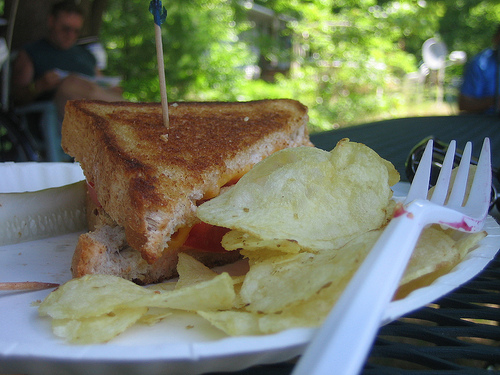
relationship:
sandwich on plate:
[46, 77, 313, 289] [2, 192, 498, 369]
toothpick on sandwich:
[122, 4, 194, 133] [46, 77, 313, 289]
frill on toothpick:
[142, 0, 174, 27] [122, 4, 194, 133]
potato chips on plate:
[30, 153, 464, 324] [2, 192, 498, 369]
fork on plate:
[303, 93, 489, 375] [2, 192, 498, 369]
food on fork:
[381, 187, 478, 240] [303, 93, 489, 375]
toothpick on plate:
[122, 4, 194, 133] [2, 192, 498, 369]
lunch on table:
[0, 93, 500, 375] [0, 110, 500, 363]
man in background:
[12, 5, 127, 156] [1, 4, 496, 160]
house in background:
[0, 3, 185, 160] [1, 4, 496, 160]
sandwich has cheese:
[46, 77, 313, 289] [70, 178, 276, 228]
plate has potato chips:
[2, 192, 498, 369] [30, 153, 464, 324]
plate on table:
[2, 192, 498, 369] [0, 110, 500, 363]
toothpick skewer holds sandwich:
[122, 4, 194, 133] [46, 77, 313, 289]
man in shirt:
[446, 30, 500, 145] [455, 47, 499, 127]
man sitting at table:
[446, 30, 500, 145] [0, 110, 500, 363]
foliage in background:
[107, 1, 461, 122] [1, 4, 496, 160]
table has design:
[0, 110, 500, 363] [322, 120, 499, 373]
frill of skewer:
[142, 0, 174, 27] [122, 4, 194, 133]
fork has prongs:
[303, 93, 489, 375] [400, 121, 499, 216]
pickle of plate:
[326, 217, 494, 308] [2, 192, 498, 369]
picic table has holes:
[0, 110, 500, 363] [409, 305, 490, 368]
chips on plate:
[30, 153, 464, 324] [2, 192, 498, 369]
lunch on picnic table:
[8, 54, 479, 346] [0, 110, 500, 363]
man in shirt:
[12, 5, 127, 156] [22, 41, 104, 106]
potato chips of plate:
[30, 153, 464, 324] [2, 192, 498, 369]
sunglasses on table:
[389, 120, 493, 216] [0, 110, 500, 363]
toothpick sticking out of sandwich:
[122, 4, 194, 133] [46, 77, 313, 289]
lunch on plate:
[8, 54, 479, 346] [2, 192, 498, 369]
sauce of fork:
[381, 187, 478, 240] [303, 93, 489, 375]